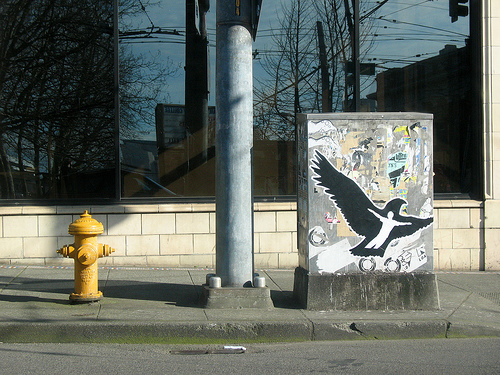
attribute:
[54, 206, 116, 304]
fire hydrant — yellow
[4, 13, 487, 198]
window — glass, large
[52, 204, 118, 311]
fire hydrant — yellow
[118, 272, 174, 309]
shadows — cast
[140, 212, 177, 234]
tile — dirty, white